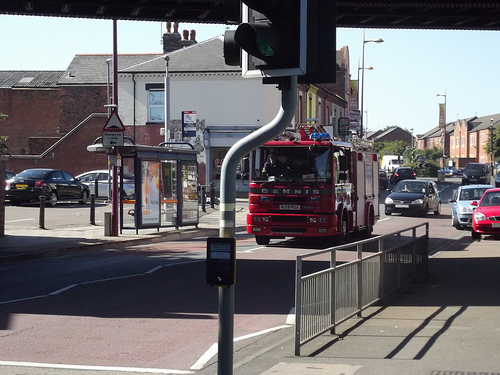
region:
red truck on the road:
[224, 108, 393, 254]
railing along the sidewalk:
[288, 210, 439, 357]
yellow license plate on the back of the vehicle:
[12, 182, 28, 192]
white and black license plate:
[272, 202, 308, 213]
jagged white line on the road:
[2, 242, 195, 324]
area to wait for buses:
[91, 125, 210, 232]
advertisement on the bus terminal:
[136, 160, 164, 224]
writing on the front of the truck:
[257, 185, 321, 196]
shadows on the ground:
[299, 250, 499, 369]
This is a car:
[378, 175, 446, 218]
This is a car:
[391, 159, 416, 187]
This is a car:
[375, 164, 394, 195]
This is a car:
[468, 184, 496, 244]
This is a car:
[460, 154, 494, 183]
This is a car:
[0, 160, 92, 212]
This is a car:
[75, 163, 153, 207]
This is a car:
[436, 161, 460, 183]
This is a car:
[383, 173, 450, 214]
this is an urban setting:
[12, 26, 443, 339]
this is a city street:
[37, 105, 447, 372]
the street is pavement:
[45, 257, 202, 367]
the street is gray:
[54, 290, 116, 372]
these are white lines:
[29, 248, 190, 312]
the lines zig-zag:
[22, 268, 232, 318]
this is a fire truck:
[261, 132, 384, 258]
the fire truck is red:
[258, 131, 373, 254]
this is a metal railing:
[283, 244, 454, 307]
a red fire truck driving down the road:
[243, 130, 375, 242]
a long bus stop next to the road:
[92, 128, 198, 230]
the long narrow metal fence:
[293, 220, 433, 352]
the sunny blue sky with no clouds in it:
[345, 29, 497, 129]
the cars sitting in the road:
[6, 163, 123, 203]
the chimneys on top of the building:
[161, 20, 196, 52]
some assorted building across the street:
[2, 35, 355, 189]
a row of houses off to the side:
[418, 113, 494, 175]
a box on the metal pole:
[203, 233, 237, 290]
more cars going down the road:
[387, 175, 499, 236]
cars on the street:
[42, 109, 476, 243]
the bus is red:
[235, 197, 352, 229]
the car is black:
[383, 191, 420, 210]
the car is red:
[471, 210, 493, 239]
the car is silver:
[446, 185, 467, 226]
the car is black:
[25, 177, 55, 199]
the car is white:
[88, 171, 115, 195]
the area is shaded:
[105, 272, 206, 314]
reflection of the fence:
[346, 303, 438, 365]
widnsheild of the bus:
[255, 148, 335, 185]